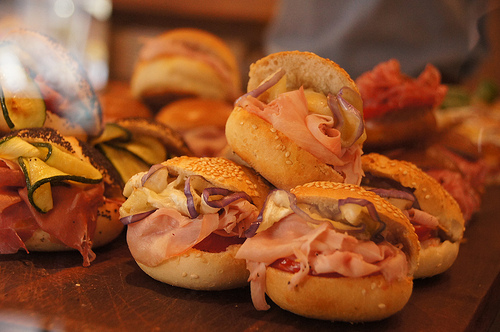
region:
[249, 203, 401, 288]
Deli meat on sandwich.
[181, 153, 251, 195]
Sesame seeds on top of bun.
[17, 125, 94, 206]
Sliced pickles on sandwich.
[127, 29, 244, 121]
Buns on sandwich.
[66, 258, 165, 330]
Wooden table holding sandwiches.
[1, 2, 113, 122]
Reflection on window glass.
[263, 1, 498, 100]
Person in the background.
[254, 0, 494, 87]
Blue shirt on person.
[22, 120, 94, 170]
Black seeds on top of bun.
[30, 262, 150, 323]
Light tan scratches on wood.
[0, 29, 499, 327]
various sandwiches on a table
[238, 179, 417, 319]
a ham sandwich on a table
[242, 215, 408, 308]
slices of ham on a kaiser bread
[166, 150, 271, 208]
bread with sesame seeds on top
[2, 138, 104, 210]
a slice of baked zucchini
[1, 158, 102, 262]
slices of prosciutto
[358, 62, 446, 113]
tomatoes on a slice of bread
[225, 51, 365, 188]
a ham sandwich with slices of purple onions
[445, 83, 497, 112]
green salad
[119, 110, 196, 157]
a bun with poppy seeds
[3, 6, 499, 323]
sandwiches on a table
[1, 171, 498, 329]
a brown table under sandwiches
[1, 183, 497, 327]
table made of wood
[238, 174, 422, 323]
a sandwich on a table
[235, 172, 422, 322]
a sandwich of ham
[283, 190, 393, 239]
onions on top a sandwich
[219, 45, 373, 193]
a sandwich over other sandwichs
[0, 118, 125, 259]
sandwich of ham and green vegetable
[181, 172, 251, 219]
slices of purple onion on sandwich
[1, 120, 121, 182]
black seeds over a sandwich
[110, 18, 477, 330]
a pile of small sandwiches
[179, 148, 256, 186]
sesame seeds on a small sandwhich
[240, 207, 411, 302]
lunch meat on a small sandwhich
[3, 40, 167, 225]
sliced zucchini on a sandwich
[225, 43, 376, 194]
an open faced sandwich on top of the pile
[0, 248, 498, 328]
wooden table underneath the sandwiches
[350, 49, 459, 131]
a pile of meat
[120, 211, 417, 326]
bottom buns of the sandwiches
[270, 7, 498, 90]
person wearing a gray shirt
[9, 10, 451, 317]
sandwiches are on display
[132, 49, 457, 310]
4 sesame seed rolls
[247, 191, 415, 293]
the ham is pink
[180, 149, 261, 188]
the seeds are white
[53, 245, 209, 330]
the table is brown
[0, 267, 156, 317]
the table is made of wood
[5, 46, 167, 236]
three poppy seed sandwiches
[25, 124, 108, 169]
the seeds are black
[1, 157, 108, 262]
the meat is reddish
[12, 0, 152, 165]
the glass is making a reflection